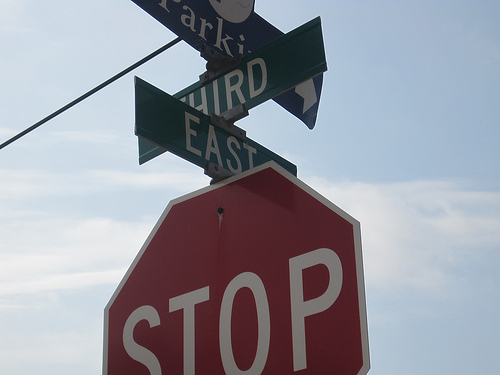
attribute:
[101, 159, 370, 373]
signpost — red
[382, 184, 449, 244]
cloud — white, fluffy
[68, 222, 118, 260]
cloud — fluffy, white